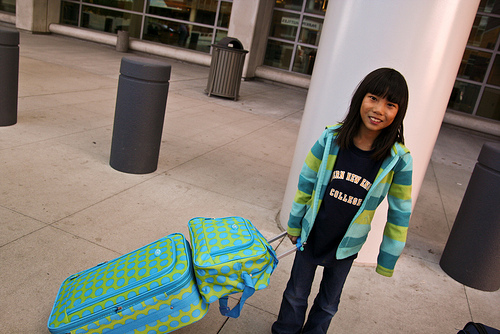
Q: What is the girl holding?
A: A suitcase.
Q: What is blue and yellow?
A: The suitcase.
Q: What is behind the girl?
A: Three gray cylinder.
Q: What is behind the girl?
A: Lg column.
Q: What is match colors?
A: The jacket and luggage.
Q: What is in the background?
A: Seventeen window panels.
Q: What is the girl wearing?
A: Tones of blue and yellow.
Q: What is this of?
A: Head of a person.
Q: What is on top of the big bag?
A: A little bag.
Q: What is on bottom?
A: This bag.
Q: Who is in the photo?
A: The girl.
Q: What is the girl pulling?
A: Luggage.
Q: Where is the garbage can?
A: Behind the girl.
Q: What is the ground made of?
A: Concrete.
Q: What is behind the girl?
A: A large column.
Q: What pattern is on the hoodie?
A: Stripes.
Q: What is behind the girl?
A: Building.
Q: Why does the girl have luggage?
A: To travel.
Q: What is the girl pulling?
A: The suitcase.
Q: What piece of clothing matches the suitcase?
A: Sweater.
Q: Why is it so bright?
A: Sunny.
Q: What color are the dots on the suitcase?
A: Blue.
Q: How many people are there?
A: One.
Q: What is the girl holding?
A: A suitcase.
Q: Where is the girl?
A: The sidewalk.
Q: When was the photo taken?
A: Day time.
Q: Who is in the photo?
A: A girl.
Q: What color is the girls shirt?
A: Black.